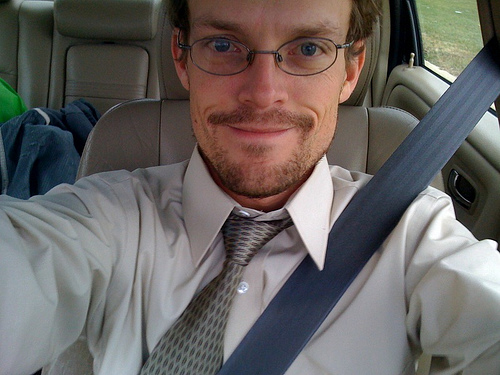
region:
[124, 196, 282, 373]
man's grey patterned tie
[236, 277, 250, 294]
button on a man's shirt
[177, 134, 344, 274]
collar on the man's shirt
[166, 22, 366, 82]
man's wire framed glasses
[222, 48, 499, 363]
seat belt crossing a man's shoulder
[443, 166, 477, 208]
door handle in the backseat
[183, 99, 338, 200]
stubby facial hair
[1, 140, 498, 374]
long sleeved white shirt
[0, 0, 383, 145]
back seat in the car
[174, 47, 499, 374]
a long gray seat belt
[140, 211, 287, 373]
part of a gray tie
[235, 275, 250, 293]
a small button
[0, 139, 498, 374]
part of a man's collared shirt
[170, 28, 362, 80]
a man's eyeglasses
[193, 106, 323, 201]
a man's brown beard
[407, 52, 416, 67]
a door lock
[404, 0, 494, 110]
a window of a vehicle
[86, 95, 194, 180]
part of a seat of a car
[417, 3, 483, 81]
a section of green grass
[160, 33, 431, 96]
man wearing thin framed glasses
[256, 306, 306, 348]
man using blue seatbelt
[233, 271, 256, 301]
shiny white button on shirt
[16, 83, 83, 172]
man has blue jacket in back seat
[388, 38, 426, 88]
door lock is open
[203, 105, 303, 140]
man has red mustache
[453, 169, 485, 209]
stainless door handle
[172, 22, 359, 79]
A pair of eyeglasses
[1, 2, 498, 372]
A man is wearing a seatbelt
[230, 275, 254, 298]
White button on a shirt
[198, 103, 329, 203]
Facial hair on man's face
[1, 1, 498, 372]
A man is sitting inside a car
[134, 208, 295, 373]
A gray tie is crooked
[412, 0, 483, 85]
A window on side of the car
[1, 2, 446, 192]
The car seats are beige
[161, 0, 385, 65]
Brown hair on man's head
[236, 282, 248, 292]
a button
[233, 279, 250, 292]
the button is white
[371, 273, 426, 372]
a white shirt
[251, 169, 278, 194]
the man has a beard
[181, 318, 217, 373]
the tie is grey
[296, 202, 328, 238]
a collard shirt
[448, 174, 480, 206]
a handle on the car door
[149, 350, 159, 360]
silver diamond on tie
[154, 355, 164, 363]
silver diamond on tie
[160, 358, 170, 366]
silver diamond on tie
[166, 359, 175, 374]
silver diamond on tie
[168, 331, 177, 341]
silver diamond on tie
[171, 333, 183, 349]
silver diamond on tie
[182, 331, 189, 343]
silver diamond on tie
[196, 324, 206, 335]
silver diamond on tie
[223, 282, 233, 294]
silver diamond on tie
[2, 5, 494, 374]
man smiling while sitting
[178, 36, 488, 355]
gray attacked seatbelt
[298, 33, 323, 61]
round blue eye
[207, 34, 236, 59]
round blue eye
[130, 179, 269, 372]
brown and gray tie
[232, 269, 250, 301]
white shirt button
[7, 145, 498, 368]
tan buttoned dress shirt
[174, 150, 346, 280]
tan shirt collar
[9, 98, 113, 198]
blue bag on back seat